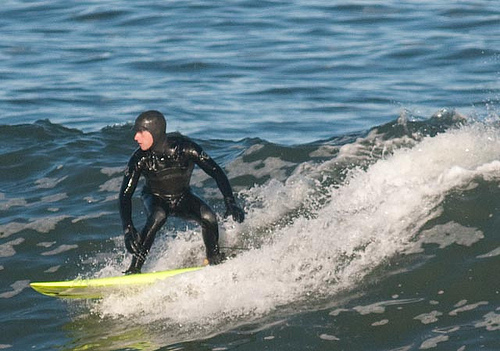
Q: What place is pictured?
A: It is an ocean.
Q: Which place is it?
A: It is an ocean.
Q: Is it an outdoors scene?
A: Yes, it is outdoors.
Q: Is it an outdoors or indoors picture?
A: It is outdoors.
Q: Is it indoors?
A: No, it is outdoors.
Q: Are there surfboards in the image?
A: Yes, there is a surfboard.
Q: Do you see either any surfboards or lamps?
A: Yes, there is a surfboard.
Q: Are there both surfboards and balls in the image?
A: No, there is a surfboard but no balls.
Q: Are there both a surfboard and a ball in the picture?
A: No, there is a surfboard but no balls.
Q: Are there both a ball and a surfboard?
A: No, there is a surfboard but no balls.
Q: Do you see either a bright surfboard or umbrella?
A: Yes, there is a bright surfboard.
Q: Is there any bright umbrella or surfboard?
A: Yes, there is a bright surfboard.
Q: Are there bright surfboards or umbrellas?
A: Yes, there is a bright surfboard.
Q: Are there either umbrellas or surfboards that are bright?
A: Yes, the surfboard is bright.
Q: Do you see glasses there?
A: No, there are no glasses.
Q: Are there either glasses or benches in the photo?
A: No, there are no glasses or benches.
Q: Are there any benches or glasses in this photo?
A: No, there are no glasses or benches.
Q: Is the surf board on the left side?
A: Yes, the surf board is on the left of the image.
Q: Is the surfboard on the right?
A: No, the surfboard is on the left of the image.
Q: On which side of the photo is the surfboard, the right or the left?
A: The surfboard is on the left of the image.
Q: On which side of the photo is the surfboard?
A: The surfboard is on the left of the image.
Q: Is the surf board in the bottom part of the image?
A: Yes, the surf board is in the bottom of the image.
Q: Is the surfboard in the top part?
A: No, the surfboard is in the bottom of the image.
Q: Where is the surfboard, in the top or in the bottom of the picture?
A: The surfboard is in the bottom of the image.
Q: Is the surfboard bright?
A: Yes, the surfboard is bright.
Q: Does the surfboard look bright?
A: Yes, the surfboard is bright.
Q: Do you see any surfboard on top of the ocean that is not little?
A: Yes, there is a surfboard on top of the ocean.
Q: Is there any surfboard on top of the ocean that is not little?
A: Yes, there is a surfboard on top of the ocean.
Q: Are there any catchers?
A: No, there are no catchers.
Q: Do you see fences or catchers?
A: No, there are no catchers or fences.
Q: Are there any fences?
A: No, there are no fences.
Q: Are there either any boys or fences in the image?
A: No, there are no fences or boys.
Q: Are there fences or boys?
A: No, there are no fences or boys.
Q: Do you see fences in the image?
A: No, there are no fences.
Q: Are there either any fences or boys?
A: No, there are no fences or boys.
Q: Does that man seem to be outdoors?
A: Yes, the man is outdoors.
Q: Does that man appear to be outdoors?
A: Yes, the man is outdoors.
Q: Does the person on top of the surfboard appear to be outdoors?
A: Yes, the man is outdoors.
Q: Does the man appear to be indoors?
A: No, the man is outdoors.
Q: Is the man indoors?
A: No, the man is outdoors.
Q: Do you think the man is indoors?
A: No, the man is outdoors.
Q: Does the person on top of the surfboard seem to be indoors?
A: No, the man is outdoors.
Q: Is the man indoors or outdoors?
A: The man is outdoors.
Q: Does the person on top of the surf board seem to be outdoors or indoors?
A: The man is outdoors.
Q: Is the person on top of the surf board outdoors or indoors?
A: The man is outdoors.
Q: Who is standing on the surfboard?
A: The man is standing on the surfboard.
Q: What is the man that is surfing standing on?
A: The man is standing on the surf board.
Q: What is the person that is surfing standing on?
A: The man is standing on the surf board.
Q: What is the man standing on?
A: The man is standing on the surf board.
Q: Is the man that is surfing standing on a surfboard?
A: Yes, the man is standing on a surfboard.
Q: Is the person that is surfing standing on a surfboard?
A: Yes, the man is standing on a surfboard.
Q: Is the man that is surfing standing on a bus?
A: No, the man is standing on a surfboard.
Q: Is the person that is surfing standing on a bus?
A: No, the man is standing on a surfboard.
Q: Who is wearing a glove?
A: The man is wearing a glove.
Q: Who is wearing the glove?
A: The man is wearing a glove.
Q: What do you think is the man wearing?
A: The man is wearing a glove.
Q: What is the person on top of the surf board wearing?
A: The man is wearing a glove.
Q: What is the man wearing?
A: The man is wearing a glove.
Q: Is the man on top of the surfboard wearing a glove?
A: Yes, the man is wearing a glove.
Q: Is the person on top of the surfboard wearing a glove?
A: Yes, the man is wearing a glove.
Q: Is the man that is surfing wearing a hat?
A: No, the man is wearing a glove.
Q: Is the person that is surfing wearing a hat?
A: No, the man is wearing a glove.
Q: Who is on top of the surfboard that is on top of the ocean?
A: The man is on top of the surfboard.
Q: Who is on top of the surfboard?
A: The man is on top of the surfboard.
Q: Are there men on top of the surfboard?
A: Yes, there is a man on top of the surfboard.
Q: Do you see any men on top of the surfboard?
A: Yes, there is a man on top of the surfboard.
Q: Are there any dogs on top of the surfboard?
A: No, there is a man on top of the surfboard.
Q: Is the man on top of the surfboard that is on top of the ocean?
A: Yes, the man is on top of the surfboard.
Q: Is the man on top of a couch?
A: No, the man is on top of the surfboard.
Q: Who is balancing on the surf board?
A: The man is balancing on the surf board.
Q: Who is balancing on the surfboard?
A: The man is balancing on the surf board.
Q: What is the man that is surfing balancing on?
A: The man is balancing on the surfboard.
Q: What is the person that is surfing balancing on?
A: The man is balancing on the surfboard.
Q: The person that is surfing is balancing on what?
A: The man is balancing on the surfboard.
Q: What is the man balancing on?
A: The man is balancing on the surfboard.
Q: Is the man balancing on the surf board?
A: Yes, the man is balancing on the surf board.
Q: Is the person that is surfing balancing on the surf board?
A: Yes, the man is balancing on the surf board.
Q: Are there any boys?
A: No, there are no boys.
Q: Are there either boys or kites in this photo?
A: No, there are no boys or kites.